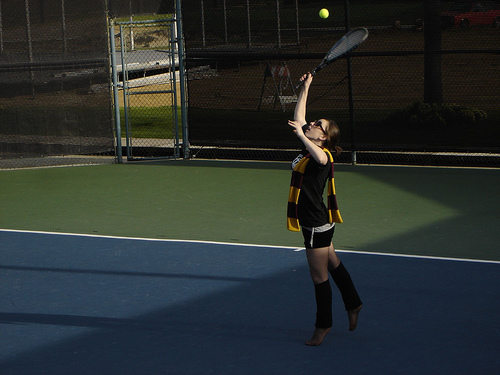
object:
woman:
[286, 72, 362, 347]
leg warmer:
[312, 278, 331, 329]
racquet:
[294, 25, 370, 89]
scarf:
[285, 148, 345, 232]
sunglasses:
[311, 117, 329, 136]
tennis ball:
[317, 6, 329, 20]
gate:
[104, 13, 188, 164]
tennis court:
[0, 158, 500, 374]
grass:
[1, 103, 497, 155]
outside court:
[2, 163, 497, 264]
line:
[0, 227, 500, 265]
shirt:
[290, 123, 337, 233]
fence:
[0, 2, 499, 173]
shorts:
[299, 221, 335, 249]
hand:
[299, 71, 315, 86]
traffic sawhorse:
[252, 58, 299, 112]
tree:
[407, 3, 468, 122]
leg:
[303, 230, 333, 347]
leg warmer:
[328, 261, 364, 316]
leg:
[328, 241, 363, 331]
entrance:
[103, 13, 182, 163]